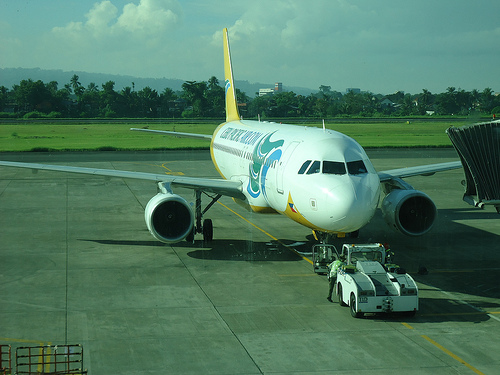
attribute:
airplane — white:
[0, 25, 463, 246]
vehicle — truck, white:
[311, 242, 420, 318]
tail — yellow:
[221, 27, 242, 121]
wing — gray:
[0, 158, 244, 201]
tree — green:
[401, 93, 418, 116]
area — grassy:
[0, 122, 474, 153]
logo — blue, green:
[246, 129, 284, 199]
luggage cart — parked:
[0, 342, 89, 375]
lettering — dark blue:
[218, 127, 263, 146]